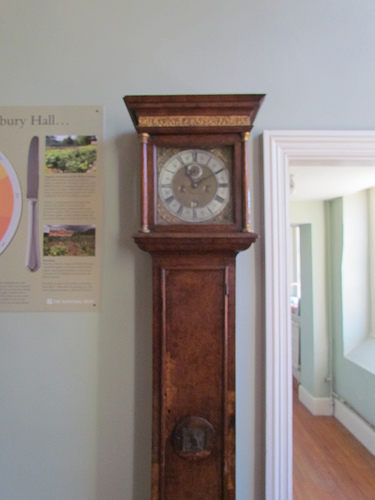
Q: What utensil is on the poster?
A: A knife.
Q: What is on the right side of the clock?
A: A doorway.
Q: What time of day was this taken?
A: Morning.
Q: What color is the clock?
A: Brown.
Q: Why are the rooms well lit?
A: Windows.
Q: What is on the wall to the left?
A: A poster.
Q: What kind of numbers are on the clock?
A: Roman numerals.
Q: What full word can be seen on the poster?
A: Hall.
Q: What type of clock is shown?
A: Grandfather clock.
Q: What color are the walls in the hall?
A: Green.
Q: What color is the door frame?
A: White.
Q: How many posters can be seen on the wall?
A: One.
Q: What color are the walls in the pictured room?
A: Blue.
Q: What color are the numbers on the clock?
A: Black.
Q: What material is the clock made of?
A: Wood.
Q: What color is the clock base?
A: Brown.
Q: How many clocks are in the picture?
A: One.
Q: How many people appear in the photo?
A: Zero.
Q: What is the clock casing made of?
A: Wood.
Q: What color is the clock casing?
A: Brown.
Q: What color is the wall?
A: Grey.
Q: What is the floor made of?
A: Wood.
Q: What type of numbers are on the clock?
A: Roman numerals.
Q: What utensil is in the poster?
A: Knife.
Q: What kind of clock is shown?
A: Grandfather clock.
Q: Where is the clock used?
A: Indoor setting.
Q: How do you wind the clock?
A: By hand.